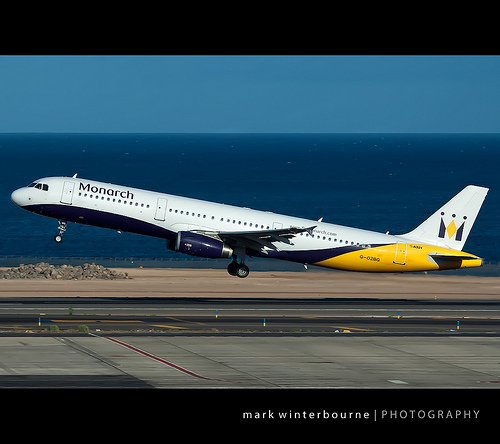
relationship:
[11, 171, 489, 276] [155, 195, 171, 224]
plane central door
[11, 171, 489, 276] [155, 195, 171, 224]
plane side door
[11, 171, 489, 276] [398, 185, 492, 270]
plane with tail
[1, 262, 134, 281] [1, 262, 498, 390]
rocks on ground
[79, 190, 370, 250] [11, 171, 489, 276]
windows on airplane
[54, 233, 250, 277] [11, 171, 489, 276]
wheels on airplane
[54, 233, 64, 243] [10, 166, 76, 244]
tire on front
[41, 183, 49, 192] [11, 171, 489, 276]
cockpit on plane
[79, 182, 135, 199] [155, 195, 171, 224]
logo near door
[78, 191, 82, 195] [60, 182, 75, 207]
windows next to door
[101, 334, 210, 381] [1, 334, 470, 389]
line on runway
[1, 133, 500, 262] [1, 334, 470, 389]
ocean next to runway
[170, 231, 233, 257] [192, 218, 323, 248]
engine under wing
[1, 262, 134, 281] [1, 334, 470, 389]
rocks next to runway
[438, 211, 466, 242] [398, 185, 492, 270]
logo on tail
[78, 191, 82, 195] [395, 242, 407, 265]
windows near yellow door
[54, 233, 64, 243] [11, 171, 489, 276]
wheels of plane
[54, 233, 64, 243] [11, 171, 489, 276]
tire of plane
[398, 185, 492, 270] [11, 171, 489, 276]
tail of plane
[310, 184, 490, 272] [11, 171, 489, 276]
design on plane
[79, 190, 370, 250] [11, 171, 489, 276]
passenger windows of plane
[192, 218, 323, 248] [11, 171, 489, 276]
side wing of plane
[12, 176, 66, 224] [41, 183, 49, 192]
cockpit planes cockpit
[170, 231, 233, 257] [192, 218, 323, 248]
engine beneath side wing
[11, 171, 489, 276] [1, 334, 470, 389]
plane above runway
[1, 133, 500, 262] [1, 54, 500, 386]
water in distance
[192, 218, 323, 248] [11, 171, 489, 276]
wing of plane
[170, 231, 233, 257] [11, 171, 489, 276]
engine under plane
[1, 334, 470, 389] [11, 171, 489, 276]
runway under plane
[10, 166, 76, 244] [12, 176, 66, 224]
front planes cockpit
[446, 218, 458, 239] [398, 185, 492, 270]
diamond on tail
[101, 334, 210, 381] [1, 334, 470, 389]
red paint on runway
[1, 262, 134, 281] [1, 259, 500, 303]
grey rock on beach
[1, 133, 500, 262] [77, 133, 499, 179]
ocean with caps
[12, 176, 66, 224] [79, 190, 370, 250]
cockpit small windows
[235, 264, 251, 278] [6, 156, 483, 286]
wheels of plane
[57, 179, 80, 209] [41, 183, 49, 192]
door to cockpit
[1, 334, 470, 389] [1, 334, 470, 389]
patch of runway